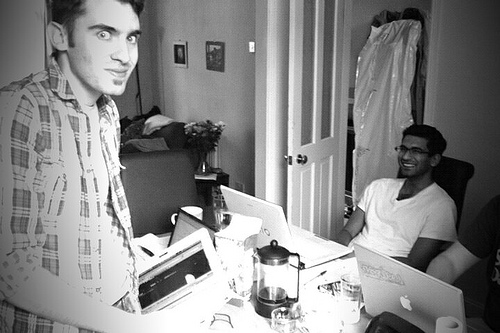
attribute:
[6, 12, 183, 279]
man — young, making, wearing, smiling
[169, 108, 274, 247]
vase — flower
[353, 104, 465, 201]
person — dark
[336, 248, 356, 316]
mug — white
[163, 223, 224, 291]
press — french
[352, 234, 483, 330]
laptop — apple, computer, open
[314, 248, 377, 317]
cup — sitting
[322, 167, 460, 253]
shirt — white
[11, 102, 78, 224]
shirt — plaid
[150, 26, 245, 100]
picture — hanging, framed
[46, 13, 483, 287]
men — sitting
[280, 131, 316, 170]
knob — silver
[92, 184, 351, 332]
table — small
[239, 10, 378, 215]
door — white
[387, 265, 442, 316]
logo — apple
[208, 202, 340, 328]
lantern — small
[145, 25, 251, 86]
photograph — hanging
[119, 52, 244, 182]
bed — messy